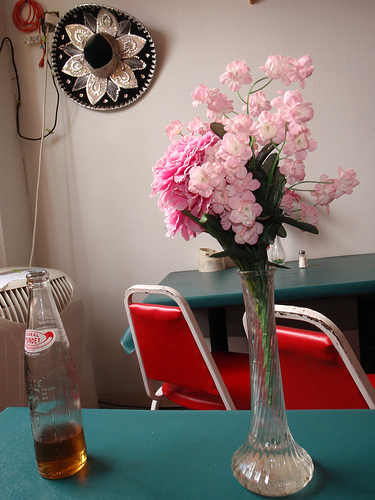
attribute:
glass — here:
[268, 233, 288, 263]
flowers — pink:
[150, 54, 361, 270]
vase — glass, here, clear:
[231, 267, 316, 497]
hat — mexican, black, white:
[51, 3, 157, 111]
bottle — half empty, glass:
[23, 272, 89, 480]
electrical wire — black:
[0, 2, 60, 142]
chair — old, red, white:
[123, 286, 250, 411]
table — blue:
[120, 253, 374, 373]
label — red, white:
[24, 329, 56, 354]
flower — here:
[221, 59, 251, 90]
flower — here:
[335, 166, 359, 196]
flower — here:
[150, 130, 220, 216]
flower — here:
[231, 223, 264, 248]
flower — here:
[289, 55, 314, 86]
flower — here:
[226, 193, 262, 224]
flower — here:
[189, 87, 218, 108]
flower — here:
[283, 99, 313, 134]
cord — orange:
[11, 0, 45, 68]